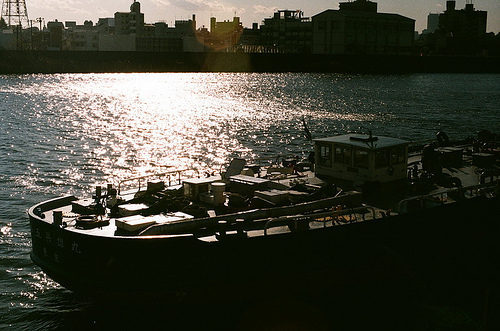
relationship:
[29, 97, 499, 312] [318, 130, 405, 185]
boat has captain room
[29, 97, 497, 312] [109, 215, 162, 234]
boat has hatch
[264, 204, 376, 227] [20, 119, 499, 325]
railing on boat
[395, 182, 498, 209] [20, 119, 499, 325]
railing on boat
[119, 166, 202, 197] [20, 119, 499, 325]
railing on boat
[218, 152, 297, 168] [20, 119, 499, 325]
railing on boat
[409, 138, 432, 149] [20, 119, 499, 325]
railing on boat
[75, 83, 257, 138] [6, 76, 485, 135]
sun reflecting from water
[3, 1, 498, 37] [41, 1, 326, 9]
white clouds in sky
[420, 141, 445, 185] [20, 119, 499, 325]
man on boat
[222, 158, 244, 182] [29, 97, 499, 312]
open hatch across middle of boat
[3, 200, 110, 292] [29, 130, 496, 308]
writing on ship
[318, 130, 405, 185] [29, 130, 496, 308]
captain room on ship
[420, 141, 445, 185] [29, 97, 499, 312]
man sitting on boat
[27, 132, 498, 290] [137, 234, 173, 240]
ship has edge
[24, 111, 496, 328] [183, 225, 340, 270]
ship has edge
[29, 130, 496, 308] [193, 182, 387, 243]
ship has edge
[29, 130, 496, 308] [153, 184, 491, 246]
ship has edge